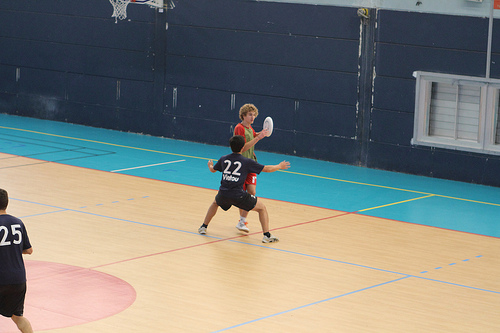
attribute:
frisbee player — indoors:
[197, 133, 290, 246]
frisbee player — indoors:
[227, 103, 277, 238]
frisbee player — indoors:
[1, 184, 31, 331]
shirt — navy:
[1, 213, 31, 286]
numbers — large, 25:
[1, 224, 23, 249]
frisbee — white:
[260, 115, 278, 137]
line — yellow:
[351, 179, 498, 213]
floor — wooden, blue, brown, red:
[0, 111, 498, 333]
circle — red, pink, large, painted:
[1, 258, 140, 333]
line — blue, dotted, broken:
[418, 250, 487, 275]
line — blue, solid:
[420, 275, 500, 299]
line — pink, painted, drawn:
[94, 238, 226, 272]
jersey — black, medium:
[213, 152, 264, 215]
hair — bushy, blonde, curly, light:
[241, 103, 260, 110]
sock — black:
[263, 233, 272, 238]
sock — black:
[201, 223, 209, 228]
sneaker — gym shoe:
[261, 234, 282, 246]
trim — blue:
[272, 238, 277, 241]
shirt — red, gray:
[233, 122, 261, 159]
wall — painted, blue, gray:
[3, 2, 500, 184]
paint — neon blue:
[329, 185, 345, 192]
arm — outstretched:
[249, 159, 295, 175]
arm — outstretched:
[208, 156, 220, 180]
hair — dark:
[229, 140, 242, 148]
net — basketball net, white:
[109, 1, 130, 21]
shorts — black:
[212, 188, 262, 213]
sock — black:
[203, 225, 208, 228]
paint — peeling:
[224, 42, 237, 53]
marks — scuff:
[357, 19, 363, 124]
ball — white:
[267, 120, 272, 123]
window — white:
[411, 68, 499, 171]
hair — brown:
[2, 191, 8, 209]